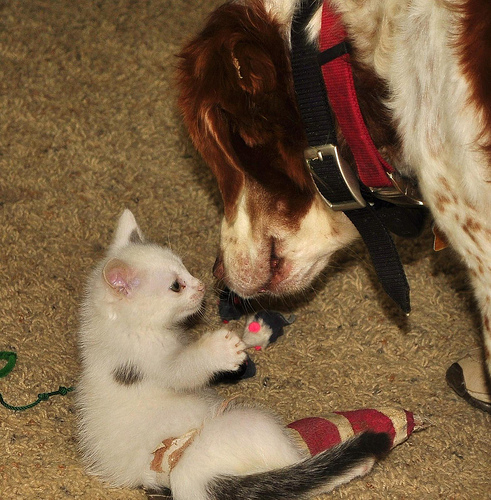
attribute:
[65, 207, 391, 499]
kitten — small, sitting, white, black, playing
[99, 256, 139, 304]
inside ear — pink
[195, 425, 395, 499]
tail — gray, black, grey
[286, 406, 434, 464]
toy — red, white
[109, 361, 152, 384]
spot — gray, brown, black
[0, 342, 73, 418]
string — green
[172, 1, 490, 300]
dog — playing, brown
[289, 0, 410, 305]
collar — black, red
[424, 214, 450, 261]
tags — gold, brown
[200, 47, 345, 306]
face — brown, white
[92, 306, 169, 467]
fur — white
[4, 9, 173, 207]
carpet — tan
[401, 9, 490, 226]
fur — white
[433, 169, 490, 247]
spots — brown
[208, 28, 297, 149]
ear — brown